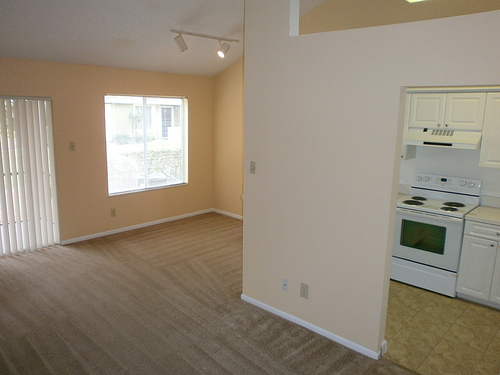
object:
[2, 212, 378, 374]
floor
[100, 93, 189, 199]
window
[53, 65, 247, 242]
wall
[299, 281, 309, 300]
electrical socket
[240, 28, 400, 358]
wall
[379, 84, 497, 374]
doorway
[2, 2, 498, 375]
room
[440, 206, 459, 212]
burner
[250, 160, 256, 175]
light switch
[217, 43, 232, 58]
ceiling light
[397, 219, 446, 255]
oven window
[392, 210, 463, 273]
oven door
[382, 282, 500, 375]
floor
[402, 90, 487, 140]
cabinet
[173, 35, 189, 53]
ceiling lights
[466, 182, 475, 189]
electric range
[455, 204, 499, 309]
cupboards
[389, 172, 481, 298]
oven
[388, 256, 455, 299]
oven hood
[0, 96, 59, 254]
blinds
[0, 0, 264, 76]
ceiling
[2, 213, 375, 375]
carpet